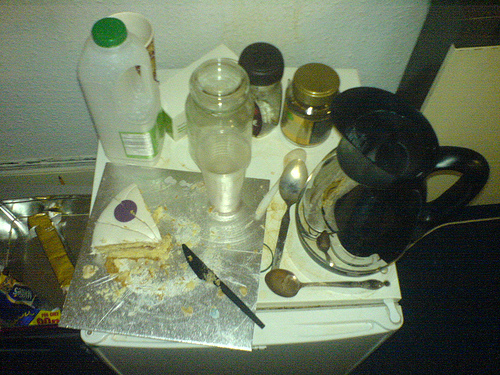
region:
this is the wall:
[172, 8, 201, 34]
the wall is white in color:
[323, 10, 378, 58]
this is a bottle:
[71, 15, 168, 157]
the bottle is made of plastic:
[87, 54, 123, 116]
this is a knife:
[180, 237, 266, 329]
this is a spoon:
[263, 263, 403, 303]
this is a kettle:
[299, 88, 499, 273]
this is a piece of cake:
[106, 203, 155, 265]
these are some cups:
[195, 142, 252, 206]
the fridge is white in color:
[283, 315, 320, 347]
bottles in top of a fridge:
[47, 17, 419, 374]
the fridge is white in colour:
[236, 265, 369, 374]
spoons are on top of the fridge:
[256, 162, 396, 330]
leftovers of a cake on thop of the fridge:
[71, 189, 238, 338]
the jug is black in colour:
[312, 41, 492, 331]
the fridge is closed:
[254, 257, 391, 372]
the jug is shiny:
[297, 69, 489, 307]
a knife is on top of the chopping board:
[178, 228, 277, 362]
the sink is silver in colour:
[0, 198, 80, 321]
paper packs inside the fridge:
[1, 200, 78, 324]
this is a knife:
[178, 248, 262, 329]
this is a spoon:
[263, 265, 386, 299]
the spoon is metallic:
[266, 260, 323, 297]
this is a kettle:
[315, 88, 445, 265]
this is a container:
[283, 70, 323, 140]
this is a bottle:
[91, 42, 131, 159]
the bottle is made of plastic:
[91, 61, 152, 143]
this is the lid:
[96, 17, 129, 37]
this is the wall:
[11, 1, 78, 152]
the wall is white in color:
[1, 22, 53, 87]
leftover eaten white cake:
[83, 176, 244, 328]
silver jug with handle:
[297, 85, 492, 292]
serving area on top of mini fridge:
[54, 4, 489, 374]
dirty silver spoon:
[264, 261, 393, 298]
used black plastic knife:
[177, 231, 268, 342]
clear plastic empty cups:
[180, 119, 257, 221]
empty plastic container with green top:
[75, 15, 167, 174]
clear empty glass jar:
[183, 52, 262, 174]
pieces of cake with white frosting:
[89, 184, 174, 271]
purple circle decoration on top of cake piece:
[114, 191, 141, 228]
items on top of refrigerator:
[64, 6, 488, 349]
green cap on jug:
[78, 16, 168, 164]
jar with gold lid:
[279, 60, 337, 146]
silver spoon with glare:
[267, 157, 309, 266]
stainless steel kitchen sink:
[0, 188, 93, 329]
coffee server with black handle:
[290, 86, 489, 275]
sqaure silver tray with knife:
[57, 160, 267, 351]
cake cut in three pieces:
[91, 180, 161, 265]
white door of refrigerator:
[248, 295, 403, 370]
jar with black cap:
[239, 41, 284, 137]